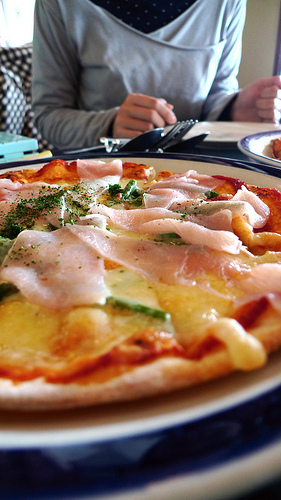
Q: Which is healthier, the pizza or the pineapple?
A: The pineapple is healthier than the pizza.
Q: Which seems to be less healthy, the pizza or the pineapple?
A: The pizza is less healthy than the pineapple.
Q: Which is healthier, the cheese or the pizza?
A: The cheese is healthier than the pizza.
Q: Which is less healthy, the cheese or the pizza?
A: The pizza is less healthy than the cheese.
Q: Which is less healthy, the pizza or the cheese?
A: The pizza is less healthy than the cheese.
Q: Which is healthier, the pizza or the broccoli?
A: The broccoli is healthier than the pizza.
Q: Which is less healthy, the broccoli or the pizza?
A: The pizza is less healthy than the broccoli.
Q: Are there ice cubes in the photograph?
A: No, there are no ice cubes.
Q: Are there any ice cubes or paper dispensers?
A: No, there are no ice cubes or paper dispensers.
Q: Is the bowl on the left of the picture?
A: No, the bowl is on the right of the image.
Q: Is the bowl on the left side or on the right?
A: The bowl is on the right of the image.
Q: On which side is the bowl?
A: The bowl is on the right of the image.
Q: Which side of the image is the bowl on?
A: The bowl is on the right of the image.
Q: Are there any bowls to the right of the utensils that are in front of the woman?
A: Yes, there is a bowl to the right of the utensils.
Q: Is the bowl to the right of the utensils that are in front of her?
A: Yes, the bowl is to the right of the utensils.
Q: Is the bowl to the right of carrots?
A: No, the bowl is to the right of the utensils.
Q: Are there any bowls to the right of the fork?
A: Yes, there is a bowl to the right of the fork.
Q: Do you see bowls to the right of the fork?
A: Yes, there is a bowl to the right of the fork.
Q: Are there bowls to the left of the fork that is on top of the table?
A: No, the bowl is to the right of the fork.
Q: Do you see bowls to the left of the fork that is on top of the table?
A: No, the bowl is to the right of the fork.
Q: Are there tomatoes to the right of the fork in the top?
A: No, there is a bowl to the right of the fork.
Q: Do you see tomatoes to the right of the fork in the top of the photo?
A: No, there is a bowl to the right of the fork.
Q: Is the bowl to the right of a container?
A: No, the bowl is to the right of the fork.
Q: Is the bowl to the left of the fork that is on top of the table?
A: No, the bowl is to the right of the fork.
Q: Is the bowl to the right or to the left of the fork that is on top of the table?
A: The bowl is to the right of the fork.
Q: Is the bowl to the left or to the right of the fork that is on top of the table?
A: The bowl is to the right of the fork.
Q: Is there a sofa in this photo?
A: Yes, there is a sofa.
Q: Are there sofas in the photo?
A: Yes, there is a sofa.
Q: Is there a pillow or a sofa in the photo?
A: Yes, there is a sofa.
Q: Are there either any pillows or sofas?
A: Yes, there is a sofa.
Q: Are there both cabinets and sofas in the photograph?
A: No, there is a sofa but no cabinets.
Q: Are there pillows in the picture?
A: No, there are no pillows.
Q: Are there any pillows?
A: No, there are no pillows.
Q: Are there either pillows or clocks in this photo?
A: No, there are no pillows or clocks.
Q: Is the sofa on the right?
A: No, the sofa is on the left of the image.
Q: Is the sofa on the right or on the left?
A: The sofa is on the left of the image.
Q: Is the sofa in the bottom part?
A: No, the sofa is in the top of the image.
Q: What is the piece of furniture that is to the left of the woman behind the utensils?
A: The piece of furniture is a sofa.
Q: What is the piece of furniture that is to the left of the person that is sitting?
A: The piece of furniture is a sofa.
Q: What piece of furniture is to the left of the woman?
A: The piece of furniture is a sofa.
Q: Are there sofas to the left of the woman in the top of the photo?
A: Yes, there is a sofa to the left of the woman.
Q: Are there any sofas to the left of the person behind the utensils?
A: Yes, there is a sofa to the left of the woman.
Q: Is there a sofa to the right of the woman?
A: No, the sofa is to the left of the woman.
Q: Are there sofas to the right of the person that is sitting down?
A: No, the sofa is to the left of the woman.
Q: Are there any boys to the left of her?
A: No, there is a sofa to the left of the woman.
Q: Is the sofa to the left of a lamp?
A: No, the sofa is to the left of the woman.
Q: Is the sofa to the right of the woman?
A: No, the sofa is to the left of the woman.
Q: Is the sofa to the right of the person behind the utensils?
A: No, the sofa is to the left of the woman.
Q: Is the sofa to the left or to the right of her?
A: The sofa is to the left of the woman.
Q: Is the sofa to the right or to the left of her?
A: The sofa is to the left of the woman.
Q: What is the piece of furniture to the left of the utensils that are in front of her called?
A: The piece of furniture is a sofa.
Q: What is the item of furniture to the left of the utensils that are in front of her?
A: The piece of furniture is a sofa.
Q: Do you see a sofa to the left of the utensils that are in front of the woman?
A: Yes, there is a sofa to the left of the utensils.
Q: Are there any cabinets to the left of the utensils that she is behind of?
A: No, there is a sofa to the left of the utensils.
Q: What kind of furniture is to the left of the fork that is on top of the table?
A: The piece of furniture is a sofa.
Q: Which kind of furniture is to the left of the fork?
A: The piece of furniture is a sofa.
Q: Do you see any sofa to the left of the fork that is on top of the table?
A: Yes, there is a sofa to the left of the fork.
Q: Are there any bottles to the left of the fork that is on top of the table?
A: No, there is a sofa to the left of the fork.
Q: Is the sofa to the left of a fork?
A: Yes, the sofa is to the left of a fork.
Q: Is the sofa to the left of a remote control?
A: No, the sofa is to the left of a fork.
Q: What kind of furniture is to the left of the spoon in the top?
A: The piece of furniture is a sofa.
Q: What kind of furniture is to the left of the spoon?
A: The piece of furniture is a sofa.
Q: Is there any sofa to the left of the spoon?
A: Yes, there is a sofa to the left of the spoon.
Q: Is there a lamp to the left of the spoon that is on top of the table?
A: No, there is a sofa to the left of the spoon.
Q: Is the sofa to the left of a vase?
A: No, the sofa is to the left of the spoon.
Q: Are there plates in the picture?
A: Yes, there is a plate.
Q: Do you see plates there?
A: Yes, there is a plate.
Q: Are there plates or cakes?
A: Yes, there is a plate.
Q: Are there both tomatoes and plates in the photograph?
A: No, there is a plate but no tomatoes.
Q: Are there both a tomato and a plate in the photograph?
A: No, there is a plate but no tomatoes.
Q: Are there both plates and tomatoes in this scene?
A: No, there is a plate but no tomatoes.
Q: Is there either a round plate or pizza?
A: Yes, there is a round plate.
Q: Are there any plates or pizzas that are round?
A: Yes, the plate is round.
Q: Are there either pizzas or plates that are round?
A: Yes, the plate is round.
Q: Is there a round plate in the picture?
A: Yes, there is a round plate.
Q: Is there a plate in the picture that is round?
A: Yes, there is a plate that is round.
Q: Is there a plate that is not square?
A: Yes, there is a round plate.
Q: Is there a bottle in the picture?
A: No, there are no bottles.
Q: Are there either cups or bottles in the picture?
A: No, there are no bottles or cups.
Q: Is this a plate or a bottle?
A: This is a plate.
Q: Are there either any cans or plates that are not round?
A: No, there is a plate but it is round.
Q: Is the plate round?
A: Yes, the plate is round.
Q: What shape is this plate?
A: The plate is round.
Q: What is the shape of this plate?
A: The plate is round.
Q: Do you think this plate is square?
A: No, the plate is round.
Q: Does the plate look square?
A: No, the plate is round.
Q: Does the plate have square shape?
A: No, the plate is round.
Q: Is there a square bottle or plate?
A: No, there is a plate but it is round.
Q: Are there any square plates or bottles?
A: No, there is a plate but it is round.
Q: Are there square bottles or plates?
A: No, there is a plate but it is round.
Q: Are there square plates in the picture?
A: No, there is a plate but it is round.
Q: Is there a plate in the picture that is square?
A: No, there is a plate but it is round.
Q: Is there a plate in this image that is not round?
A: No, there is a plate but it is round.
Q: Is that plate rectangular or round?
A: The plate is round.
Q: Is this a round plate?
A: Yes, this is a round plate.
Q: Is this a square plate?
A: No, this is a round plate.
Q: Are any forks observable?
A: Yes, there is a fork.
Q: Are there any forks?
A: Yes, there is a fork.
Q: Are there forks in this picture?
A: Yes, there is a fork.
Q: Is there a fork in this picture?
A: Yes, there is a fork.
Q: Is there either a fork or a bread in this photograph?
A: Yes, there is a fork.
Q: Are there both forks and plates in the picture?
A: Yes, there are both a fork and a plate.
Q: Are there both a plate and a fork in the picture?
A: Yes, there are both a fork and a plate.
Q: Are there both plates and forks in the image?
A: Yes, there are both a fork and a plate.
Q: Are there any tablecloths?
A: No, there are no tablecloths.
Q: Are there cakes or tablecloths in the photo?
A: No, there are no tablecloths or cakes.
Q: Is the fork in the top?
A: Yes, the fork is in the top of the image.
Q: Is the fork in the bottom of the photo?
A: No, the fork is in the top of the image.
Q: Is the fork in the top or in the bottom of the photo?
A: The fork is in the top of the image.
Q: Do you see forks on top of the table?
A: Yes, there is a fork on top of the table.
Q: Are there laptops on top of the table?
A: No, there is a fork on top of the table.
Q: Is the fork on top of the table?
A: Yes, the fork is on top of the table.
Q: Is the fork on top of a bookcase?
A: No, the fork is on top of the table.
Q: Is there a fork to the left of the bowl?
A: Yes, there is a fork to the left of the bowl.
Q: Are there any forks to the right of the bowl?
A: No, the fork is to the left of the bowl.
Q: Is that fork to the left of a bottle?
A: No, the fork is to the left of the bowl.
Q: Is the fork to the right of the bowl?
A: No, the fork is to the left of the bowl.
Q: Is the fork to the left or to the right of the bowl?
A: The fork is to the left of the bowl.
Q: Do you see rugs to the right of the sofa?
A: No, there is a fork to the right of the sofa.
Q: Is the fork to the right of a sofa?
A: Yes, the fork is to the right of a sofa.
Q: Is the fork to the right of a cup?
A: No, the fork is to the right of a sofa.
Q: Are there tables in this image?
A: Yes, there is a table.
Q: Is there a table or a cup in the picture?
A: Yes, there is a table.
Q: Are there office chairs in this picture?
A: No, there are no office chairs.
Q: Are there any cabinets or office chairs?
A: No, there are no office chairs or cabinets.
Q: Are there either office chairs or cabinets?
A: No, there are no office chairs or cabinets.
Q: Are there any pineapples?
A: Yes, there is a pineapple.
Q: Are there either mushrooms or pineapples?
A: Yes, there is a pineapple.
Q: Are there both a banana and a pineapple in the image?
A: No, there is a pineapple but no bananas.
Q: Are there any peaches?
A: No, there are no peaches.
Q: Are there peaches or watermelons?
A: No, there are no peaches or watermelons.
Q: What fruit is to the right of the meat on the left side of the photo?
A: The fruit is a pineapple.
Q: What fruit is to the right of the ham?
A: The fruit is a pineapple.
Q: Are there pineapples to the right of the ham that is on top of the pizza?
A: Yes, there is a pineapple to the right of the ham.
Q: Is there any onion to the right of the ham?
A: No, there is a pineapple to the right of the ham.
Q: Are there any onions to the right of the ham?
A: No, there is a pineapple to the right of the ham.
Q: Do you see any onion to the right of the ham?
A: No, there is a pineapple to the right of the ham.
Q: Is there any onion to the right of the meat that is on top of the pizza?
A: No, there is a pineapple to the right of the ham.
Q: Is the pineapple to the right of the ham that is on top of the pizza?
A: Yes, the pineapple is to the right of the ham.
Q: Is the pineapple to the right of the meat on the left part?
A: Yes, the pineapple is to the right of the ham.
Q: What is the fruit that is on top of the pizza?
A: The fruit is a pineapple.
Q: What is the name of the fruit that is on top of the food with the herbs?
A: The fruit is a pineapple.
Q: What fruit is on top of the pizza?
A: The fruit is a pineapple.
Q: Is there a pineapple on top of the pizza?
A: Yes, there is a pineapple on top of the pizza.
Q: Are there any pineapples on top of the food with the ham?
A: Yes, there is a pineapple on top of the pizza.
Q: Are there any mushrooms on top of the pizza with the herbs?
A: No, there is a pineapple on top of the pizza.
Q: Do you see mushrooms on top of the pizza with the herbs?
A: No, there is a pineapple on top of the pizza.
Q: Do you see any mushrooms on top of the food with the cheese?
A: No, there is a pineapple on top of the pizza.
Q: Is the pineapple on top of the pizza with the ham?
A: Yes, the pineapple is on top of the pizza.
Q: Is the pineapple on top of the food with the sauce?
A: Yes, the pineapple is on top of the pizza.